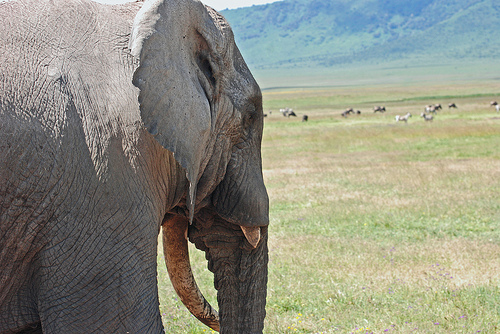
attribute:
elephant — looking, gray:
[1, 0, 271, 334]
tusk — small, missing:
[240, 226, 260, 247]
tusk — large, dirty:
[163, 215, 220, 332]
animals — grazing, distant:
[263, 101, 499, 127]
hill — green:
[218, 1, 500, 74]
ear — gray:
[129, 0, 222, 220]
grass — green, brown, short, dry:
[160, 70, 500, 333]